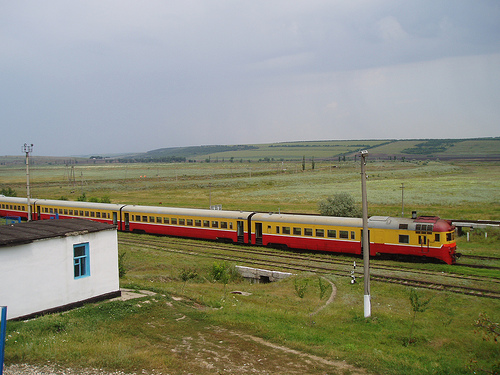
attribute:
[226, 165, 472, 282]
train — yellow, long, red, passenger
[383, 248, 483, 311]
tracks — brown, empty, railroad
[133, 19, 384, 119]
sky — gray, cloudy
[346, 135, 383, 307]
pole — beside, wood, telephone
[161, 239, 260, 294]
grass — dead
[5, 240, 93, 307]
building — white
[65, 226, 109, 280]
window — trimmed, blue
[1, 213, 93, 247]
roof — brown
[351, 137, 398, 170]
lights — above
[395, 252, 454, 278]
concrete — under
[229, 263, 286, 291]
entrance — under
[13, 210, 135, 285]
buliding — small